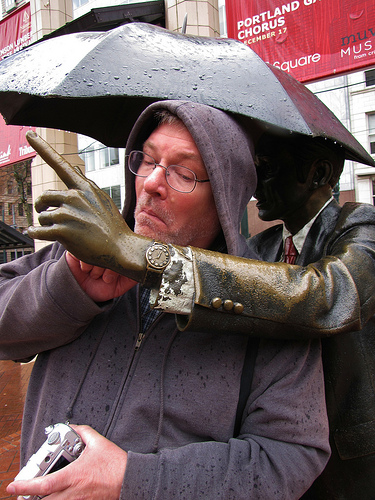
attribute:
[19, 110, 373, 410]
statue — copper, pointing, bronze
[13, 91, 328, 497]
man — white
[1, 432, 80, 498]
camera — grey, silver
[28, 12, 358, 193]
umbrella — metal, black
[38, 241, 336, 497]
sweatshirt — grey, black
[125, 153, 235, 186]
glasses — wire-rim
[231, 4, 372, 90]
sign — red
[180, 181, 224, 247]
skin — red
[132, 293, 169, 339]
shirt — plaid